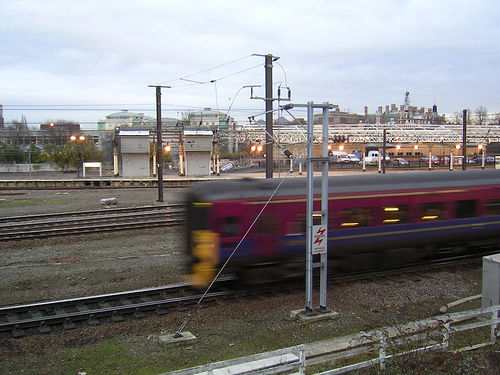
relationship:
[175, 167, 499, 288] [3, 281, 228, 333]
train speeding down track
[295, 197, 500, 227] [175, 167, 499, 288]
windows on side of train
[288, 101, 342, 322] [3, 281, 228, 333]
pole beside track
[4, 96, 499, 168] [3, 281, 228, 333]
power lines over track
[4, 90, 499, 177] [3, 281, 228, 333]
buildings on side of track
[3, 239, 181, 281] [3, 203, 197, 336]
gravel between tracks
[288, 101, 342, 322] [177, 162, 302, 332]
pole held up by line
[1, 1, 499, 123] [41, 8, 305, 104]
sky covered in clouds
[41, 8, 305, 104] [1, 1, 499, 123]
clouds in sky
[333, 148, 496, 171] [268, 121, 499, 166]
vehicles parked in front of building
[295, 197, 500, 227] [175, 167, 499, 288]
windows on train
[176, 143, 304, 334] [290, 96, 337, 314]
stabilizing wire for utility pole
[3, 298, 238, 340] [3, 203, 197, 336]
railroad ties under tracks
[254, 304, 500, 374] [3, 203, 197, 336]
fence near tracks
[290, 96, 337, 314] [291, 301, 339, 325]
utility pole sitting on footer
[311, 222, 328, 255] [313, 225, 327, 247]
sign has lightning bolts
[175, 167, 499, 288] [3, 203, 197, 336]
train speeding down tracks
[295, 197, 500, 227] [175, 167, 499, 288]
windows along side of train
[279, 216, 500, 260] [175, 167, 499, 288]
stripe down side of train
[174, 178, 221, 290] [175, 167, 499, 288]
front of train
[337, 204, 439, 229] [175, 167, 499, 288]
lights inside of train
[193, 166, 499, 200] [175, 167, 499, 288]
top of train